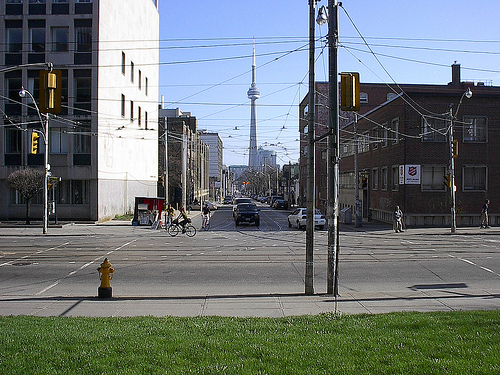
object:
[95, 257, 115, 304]
fire hydrant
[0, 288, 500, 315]
sidewalk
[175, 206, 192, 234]
person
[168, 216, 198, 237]
bike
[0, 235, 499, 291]
street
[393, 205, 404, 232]
person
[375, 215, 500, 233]
sidewalk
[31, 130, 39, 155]
cover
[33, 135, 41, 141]
traffic light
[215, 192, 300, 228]
street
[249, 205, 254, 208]
people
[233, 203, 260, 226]
vehicle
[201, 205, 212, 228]
people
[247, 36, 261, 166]
building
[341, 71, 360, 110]
street light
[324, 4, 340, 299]
utility pole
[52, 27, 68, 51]
windows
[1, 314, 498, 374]
grass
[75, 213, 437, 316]
intersection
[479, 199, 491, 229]
man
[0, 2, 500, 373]
city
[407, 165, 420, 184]
logo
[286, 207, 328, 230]
car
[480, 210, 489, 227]
pants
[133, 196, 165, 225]
newstand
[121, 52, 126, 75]
windows